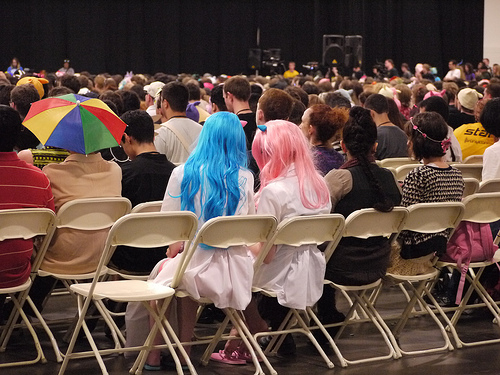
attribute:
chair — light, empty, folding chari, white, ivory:
[57, 209, 199, 373]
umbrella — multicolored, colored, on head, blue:
[20, 91, 129, 157]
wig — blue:
[165, 109, 248, 228]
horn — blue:
[256, 122, 268, 132]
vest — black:
[326, 164, 403, 287]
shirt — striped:
[0, 148, 56, 290]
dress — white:
[127, 162, 257, 313]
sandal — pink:
[209, 346, 251, 367]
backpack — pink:
[443, 221, 495, 310]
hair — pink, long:
[249, 119, 332, 213]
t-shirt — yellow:
[449, 122, 498, 160]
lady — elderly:
[9, 56, 23, 74]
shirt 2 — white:
[152, 115, 205, 168]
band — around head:
[407, 115, 452, 152]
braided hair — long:
[341, 105, 394, 215]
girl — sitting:
[222, 115, 332, 365]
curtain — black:
[1, 0, 484, 74]